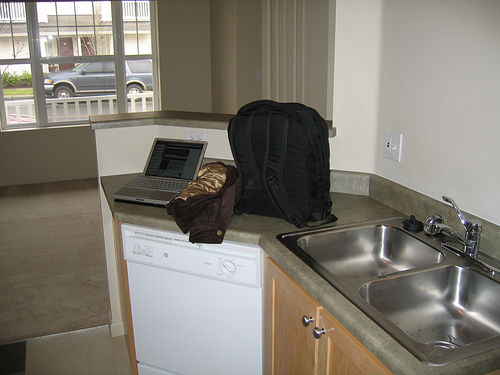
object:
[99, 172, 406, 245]
counter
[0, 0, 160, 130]
window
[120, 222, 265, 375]
dishwasher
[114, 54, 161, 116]
frame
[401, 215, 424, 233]
black/sink stopper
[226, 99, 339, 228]
black/back pack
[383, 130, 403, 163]
outlet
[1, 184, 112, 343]
carpet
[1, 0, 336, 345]
living room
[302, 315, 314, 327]
hardware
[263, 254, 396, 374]
cabinets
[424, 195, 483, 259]
faucet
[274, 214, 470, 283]
sink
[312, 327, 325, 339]
knobs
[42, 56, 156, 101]
car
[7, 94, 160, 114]
road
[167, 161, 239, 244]
coat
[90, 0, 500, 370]
kitchen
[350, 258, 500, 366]
sink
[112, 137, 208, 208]
computer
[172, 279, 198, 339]
part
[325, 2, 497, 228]
wall